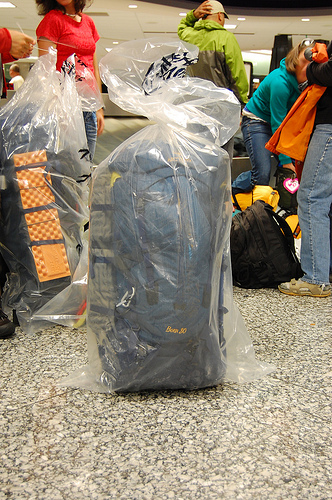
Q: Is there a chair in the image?
A: No, there are no chairs.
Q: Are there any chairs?
A: No, there are no chairs.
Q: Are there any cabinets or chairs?
A: No, there are no chairs or cabinets.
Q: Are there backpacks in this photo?
A: Yes, there is a backpack.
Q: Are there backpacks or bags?
A: Yes, there is a backpack.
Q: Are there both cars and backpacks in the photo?
A: No, there is a backpack but no cars.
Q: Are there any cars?
A: No, there are no cars.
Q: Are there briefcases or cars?
A: No, there are no cars or briefcases.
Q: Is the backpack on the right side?
A: Yes, the backpack is on the right of the image.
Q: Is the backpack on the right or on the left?
A: The backpack is on the right of the image.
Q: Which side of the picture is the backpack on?
A: The backpack is on the right of the image.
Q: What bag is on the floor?
A: The bag is a backpack.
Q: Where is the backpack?
A: The backpack is on the floor.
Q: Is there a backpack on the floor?
A: Yes, there is a backpack on the floor.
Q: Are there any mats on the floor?
A: No, there is a backpack on the floor.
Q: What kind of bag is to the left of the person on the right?
A: The bag is a backpack.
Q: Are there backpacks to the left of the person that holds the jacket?
A: Yes, there is a backpack to the left of the person.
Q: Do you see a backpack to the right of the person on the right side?
A: No, the backpack is to the left of the person.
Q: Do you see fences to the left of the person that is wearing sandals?
A: No, there is a backpack to the left of the person.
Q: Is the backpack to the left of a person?
A: Yes, the backpack is to the left of a person.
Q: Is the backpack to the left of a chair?
A: No, the backpack is to the left of a person.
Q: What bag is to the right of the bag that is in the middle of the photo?
A: The bag is a backpack.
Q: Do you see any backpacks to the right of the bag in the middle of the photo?
A: Yes, there is a backpack to the right of the bag.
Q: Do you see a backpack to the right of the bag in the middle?
A: Yes, there is a backpack to the right of the bag.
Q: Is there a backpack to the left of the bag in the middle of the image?
A: No, the backpack is to the right of the bag.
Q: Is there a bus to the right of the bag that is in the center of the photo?
A: No, there is a backpack to the right of the bag.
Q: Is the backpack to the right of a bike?
A: No, the backpack is to the right of the bag.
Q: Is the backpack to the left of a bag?
A: No, the backpack is to the right of a bag.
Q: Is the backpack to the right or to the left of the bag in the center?
A: The backpack is to the right of the bag.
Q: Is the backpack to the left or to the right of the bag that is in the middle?
A: The backpack is to the right of the bag.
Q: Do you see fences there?
A: No, there are no fences.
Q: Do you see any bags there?
A: Yes, there is a bag.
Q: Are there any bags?
A: Yes, there is a bag.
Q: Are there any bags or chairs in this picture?
A: Yes, there is a bag.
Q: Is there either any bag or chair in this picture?
A: Yes, there is a bag.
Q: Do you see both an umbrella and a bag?
A: No, there is a bag but no umbrellas.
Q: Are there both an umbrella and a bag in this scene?
A: No, there is a bag but no umbrellas.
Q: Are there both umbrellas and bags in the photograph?
A: No, there is a bag but no umbrellas.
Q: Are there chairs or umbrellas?
A: No, there are no chairs or umbrellas.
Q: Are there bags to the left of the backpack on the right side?
A: Yes, there is a bag to the left of the backpack.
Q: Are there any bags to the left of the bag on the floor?
A: Yes, there is a bag to the left of the backpack.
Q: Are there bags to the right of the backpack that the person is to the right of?
A: No, the bag is to the left of the backpack.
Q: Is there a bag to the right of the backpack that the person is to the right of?
A: No, the bag is to the left of the backpack.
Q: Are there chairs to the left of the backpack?
A: No, there is a bag to the left of the backpack.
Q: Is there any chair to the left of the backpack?
A: No, there is a bag to the left of the backpack.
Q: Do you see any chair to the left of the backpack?
A: No, there is a bag to the left of the backpack.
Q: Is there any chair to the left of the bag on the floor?
A: No, there is a bag to the left of the backpack.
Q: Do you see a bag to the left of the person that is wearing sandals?
A: Yes, there is a bag to the left of the person.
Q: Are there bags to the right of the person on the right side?
A: No, the bag is to the left of the person.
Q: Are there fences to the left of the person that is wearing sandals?
A: No, there is a bag to the left of the person.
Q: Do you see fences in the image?
A: No, there are no fences.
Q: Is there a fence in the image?
A: No, there are no fences.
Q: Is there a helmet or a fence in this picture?
A: No, there are no fences or helmets.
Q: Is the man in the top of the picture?
A: Yes, the man is in the top of the image.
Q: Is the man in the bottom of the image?
A: No, the man is in the top of the image.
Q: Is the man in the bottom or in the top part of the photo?
A: The man is in the top of the image.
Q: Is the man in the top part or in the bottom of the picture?
A: The man is in the top of the image.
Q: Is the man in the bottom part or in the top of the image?
A: The man is in the top of the image.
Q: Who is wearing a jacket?
A: The man is wearing a jacket.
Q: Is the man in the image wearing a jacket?
A: Yes, the man is wearing a jacket.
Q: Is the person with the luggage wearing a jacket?
A: Yes, the man is wearing a jacket.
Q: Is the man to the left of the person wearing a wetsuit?
A: No, the man is wearing a jacket.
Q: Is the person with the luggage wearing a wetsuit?
A: No, the man is wearing a jacket.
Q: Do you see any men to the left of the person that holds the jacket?
A: Yes, there is a man to the left of the person.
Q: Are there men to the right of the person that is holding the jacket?
A: No, the man is to the left of the person.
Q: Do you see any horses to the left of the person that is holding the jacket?
A: No, there is a man to the left of the person.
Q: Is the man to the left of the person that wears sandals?
A: Yes, the man is to the left of the person.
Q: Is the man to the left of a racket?
A: No, the man is to the left of the person.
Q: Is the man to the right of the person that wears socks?
A: No, the man is to the left of the person.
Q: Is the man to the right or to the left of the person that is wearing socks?
A: The man is to the left of the person.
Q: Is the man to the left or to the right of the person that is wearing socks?
A: The man is to the left of the person.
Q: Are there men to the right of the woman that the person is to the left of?
A: Yes, there is a man to the right of the woman.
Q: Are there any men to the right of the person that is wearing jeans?
A: Yes, there is a man to the right of the woman.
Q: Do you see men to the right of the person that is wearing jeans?
A: Yes, there is a man to the right of the woman.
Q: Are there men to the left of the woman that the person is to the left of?
A: No, the man is to the right of the woman.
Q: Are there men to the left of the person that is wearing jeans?
A: No, the man is to the right of the woman.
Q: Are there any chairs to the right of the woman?
A: No, there is a man to the right of the woman.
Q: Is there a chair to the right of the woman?
A: No, there is a man to the right of the woman.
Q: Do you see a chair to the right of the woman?
A: No, there is a man to the right of the woman.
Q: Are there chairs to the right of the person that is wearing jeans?
A: No, there is a man to the right of the woman.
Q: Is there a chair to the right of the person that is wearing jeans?
A: No, there is a man to the right of the woman.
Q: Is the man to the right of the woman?
A: Yes, the man is to the right of the woman.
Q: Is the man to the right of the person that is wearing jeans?
A: Yes, the man is to the right of the woman.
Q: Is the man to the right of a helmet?
A: No, the man is to the right of the woman.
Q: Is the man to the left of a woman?
A: No, the man is to the right of a woman.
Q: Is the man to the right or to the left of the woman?
A: The man is to the right of the woman.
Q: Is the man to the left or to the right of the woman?
A: The man is to the right of the woman.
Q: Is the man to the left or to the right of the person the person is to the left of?
A: The man is to the right of the woman.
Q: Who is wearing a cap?
A: The man is wearing a cap.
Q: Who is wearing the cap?
A: The man is wearing a cap.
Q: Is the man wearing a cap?
A: Yes, the man is wearing a cap.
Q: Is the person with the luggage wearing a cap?
A: Yes, the man is wearing a cap.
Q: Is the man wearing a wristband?
A: No, the man is wearing a cap.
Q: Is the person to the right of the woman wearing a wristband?
A: No, the man is wearing a cap.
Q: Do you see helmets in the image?
A: No, there are no helmets.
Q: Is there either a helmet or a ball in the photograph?
A: No, there are no helmets or balls.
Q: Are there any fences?
A: No, there are no fences.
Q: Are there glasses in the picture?
A: No, there are no glasses.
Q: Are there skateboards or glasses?
A: No, there are no glasses or skateboards.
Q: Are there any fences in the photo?
A: No, there are no fences.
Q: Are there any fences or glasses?
A: No, there are no fences or glasses.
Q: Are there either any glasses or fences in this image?
A: No, there are no fences or glasses.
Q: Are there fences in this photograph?
A: No, there are no fences.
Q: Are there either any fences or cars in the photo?
A: No, there are no fences or cars.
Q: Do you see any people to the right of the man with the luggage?
A: Yes, there is a person to the right of the man.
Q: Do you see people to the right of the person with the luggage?
A: Yes, there is a person to the right of the man.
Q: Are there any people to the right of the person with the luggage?
A: Yes, there is a person to the right of the man.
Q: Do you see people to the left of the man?
A: No, the person is to the right of the man.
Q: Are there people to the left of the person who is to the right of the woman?
A: No, the person is to the right of the man.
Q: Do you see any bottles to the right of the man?
A: No, there is a person to the right of the man.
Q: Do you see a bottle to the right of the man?
A: No, there is a person to the right of the man.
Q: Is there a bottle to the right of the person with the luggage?
A: No, there is a person to the right of the man.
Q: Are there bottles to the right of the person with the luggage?
A: No, there is a person to the right of the man.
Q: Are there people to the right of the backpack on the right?
A: Yes, there is a person to the right of the backpack.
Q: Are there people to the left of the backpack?
A: No, the person is to the right of the backpack.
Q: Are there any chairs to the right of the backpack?
A: No, there is a person to the right of the backpack.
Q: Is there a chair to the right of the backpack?
A: No, there is a person to the right of the backpack.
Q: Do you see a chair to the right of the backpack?
A: No, there is a person to the right of the backpack.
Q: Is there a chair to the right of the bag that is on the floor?
A: No, there is a person to the right of the backpack.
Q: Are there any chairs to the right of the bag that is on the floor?
A: No, there is a person to the right of the backpack.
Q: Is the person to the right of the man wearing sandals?
A: Yes, the person is wearing sandals.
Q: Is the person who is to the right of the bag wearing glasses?
A: No, the person is wearing sandals.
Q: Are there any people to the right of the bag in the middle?
A: Yes, there is a person to the right of the bag.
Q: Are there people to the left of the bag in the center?
A: No, the person is to the right of the bag.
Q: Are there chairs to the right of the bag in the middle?
A: No, there is a person to the right of the bag.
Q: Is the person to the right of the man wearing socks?
A: Yes, the person is wearing socks.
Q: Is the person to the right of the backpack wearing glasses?
A: No, the person is wearing socks.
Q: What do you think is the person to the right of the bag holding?
A: The person is holding the jacket.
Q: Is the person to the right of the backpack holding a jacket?
A: Yes, the person is holding a jacket.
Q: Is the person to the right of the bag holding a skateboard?
A: No, the person is holding a jacket.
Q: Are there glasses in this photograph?
A: No, there are no glasses.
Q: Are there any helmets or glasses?
A: No, there are no glasses or helmets.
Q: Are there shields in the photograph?
A: No, there are no shields.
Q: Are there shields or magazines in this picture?
A: No, there are no shields or magazines.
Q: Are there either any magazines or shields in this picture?
A: No, there are no shields or magazines.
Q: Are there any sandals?
A: Yes, there are sandals.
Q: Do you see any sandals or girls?
A: Yes, there are sandals.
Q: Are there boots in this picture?
A: No, there are no boots.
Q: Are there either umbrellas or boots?
A: No, there are no boots or umbrellas.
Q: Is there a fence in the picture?
A: No, there are no fences.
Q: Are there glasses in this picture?
A: No, there are no glasses.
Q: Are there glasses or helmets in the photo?
A: No, there are no glasses or helmets.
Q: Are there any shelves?
A: No, there are no shelves.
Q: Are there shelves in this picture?
A: No, there are no shelves.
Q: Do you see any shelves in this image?
A: No, there are no shelves.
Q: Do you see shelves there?
A: No, there are no shelves.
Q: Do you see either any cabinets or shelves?
A: No, there are no shelves or cabinets.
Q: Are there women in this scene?
A: Yes, there is a woman.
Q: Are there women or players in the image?
A: Yes, there is a woman.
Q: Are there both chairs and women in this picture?
A: No, there is a woman but no chairs.